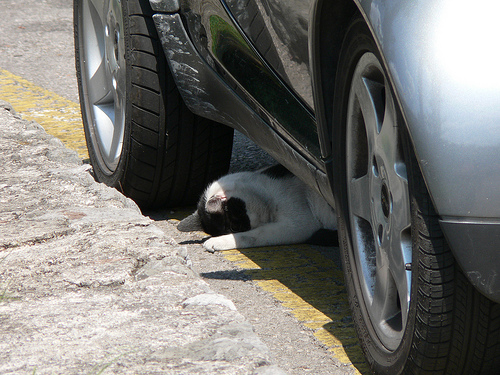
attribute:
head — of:
[171, 157, 276, 246]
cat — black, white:
[173, 173, 314, 247]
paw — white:
[201, 232, 234, 254]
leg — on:
[193, 224, 313, 248]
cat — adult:
[164, 157, 334, 254]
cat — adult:
[177, 170, 338, 252]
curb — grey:
[43, 157, 235, 369]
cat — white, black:
[160, 162, 328, 260]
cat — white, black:
[166, 156, 344, 265]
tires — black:
[327, 6, 497, 372]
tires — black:
[70, 0, 234, 213]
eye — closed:
[212, 197, 254, 221]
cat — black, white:
[173, 161, 340, 253]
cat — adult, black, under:
[175, 157, 322, 262]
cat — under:
[188, 165, 318, 254]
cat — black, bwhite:
[158, 114, 320, 276]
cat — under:
[174, 144, 339, 259]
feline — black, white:
[173, 152, 344, 254]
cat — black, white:
[179, 156, 349, 258]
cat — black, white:
[138, 155, 345, 248]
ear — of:
[172, 210, 202, 239]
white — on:
[274, 193, 308, 230]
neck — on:
[229, 167, 285, 211]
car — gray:
[71, 4, 494, 373]